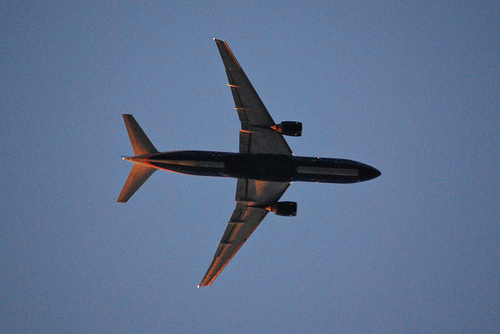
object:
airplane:
[115, 36, 382, 290]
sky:
[3, 2, 497, 334]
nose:
[366, 166, 383, 179]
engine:
[272, 119, 303, 137]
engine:
[272, 201, 298, 217]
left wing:
[196, 177, 289, 289]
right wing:
[209, 37, 295, 152]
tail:
[118, 154, 129, 160]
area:
[296, 166, 359, 175]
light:
[196, 283, 202, 288]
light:
[212, 37, 216, 40]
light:
[122, 157, 125, 160]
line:
[147, 159, 225, 169]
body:
[121, 149, 382, 185]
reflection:
[124, 128, 154, 190]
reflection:
[200, 238, 244, 289]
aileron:
[217, 241, 240, 246]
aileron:
[226, 83, 239, 88]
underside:
[157, 151, 382, 183]